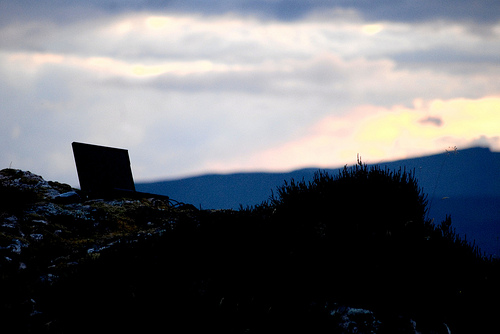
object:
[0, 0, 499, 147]
sky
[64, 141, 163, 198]
box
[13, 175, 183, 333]
hillside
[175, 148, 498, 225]
mountains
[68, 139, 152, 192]
laptop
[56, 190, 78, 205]
rocks